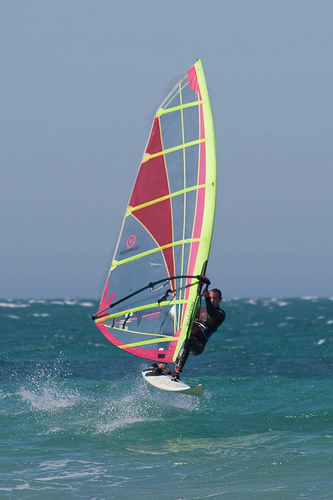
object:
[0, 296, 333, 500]
water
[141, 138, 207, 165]
strip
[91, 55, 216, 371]
sail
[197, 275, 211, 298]
handle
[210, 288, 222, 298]
hair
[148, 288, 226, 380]
man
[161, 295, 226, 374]
wet suit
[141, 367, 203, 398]
board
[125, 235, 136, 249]
target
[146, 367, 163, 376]
pole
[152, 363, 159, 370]
holes